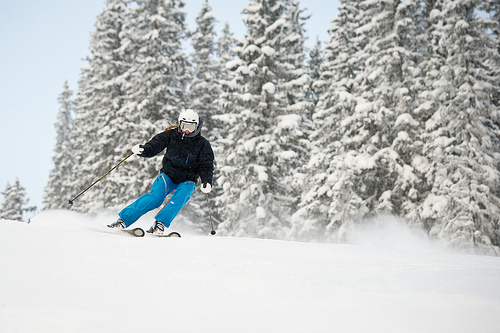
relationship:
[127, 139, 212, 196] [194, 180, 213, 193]
gloves on skiers hands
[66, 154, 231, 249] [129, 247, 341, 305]
skis on snow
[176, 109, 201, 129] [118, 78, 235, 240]
helmet on skier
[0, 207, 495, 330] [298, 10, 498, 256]
snow on trees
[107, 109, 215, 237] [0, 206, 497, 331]
lady on hill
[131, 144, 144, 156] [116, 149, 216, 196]
gloves on hands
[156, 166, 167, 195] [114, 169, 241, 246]
zipper on pants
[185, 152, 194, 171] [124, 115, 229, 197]
line on jacket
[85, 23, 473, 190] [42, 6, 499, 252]
snow on trees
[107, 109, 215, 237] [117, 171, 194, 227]
lady wears pants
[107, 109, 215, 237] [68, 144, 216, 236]
lady holds black poles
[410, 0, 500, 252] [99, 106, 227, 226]
pine tree behind skier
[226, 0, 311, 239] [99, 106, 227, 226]
pine tree behind skier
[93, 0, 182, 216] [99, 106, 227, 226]
pine tree behind skier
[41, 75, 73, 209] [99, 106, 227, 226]
pine tree behind skier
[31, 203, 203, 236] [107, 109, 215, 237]
puff kicked up by lady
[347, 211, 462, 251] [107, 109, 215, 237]
puff kicked up by lady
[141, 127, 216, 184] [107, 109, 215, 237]
jacket on lady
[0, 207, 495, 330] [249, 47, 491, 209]
snow on trees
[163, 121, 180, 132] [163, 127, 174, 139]
hair on shoulder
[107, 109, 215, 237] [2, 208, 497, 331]
lady in snow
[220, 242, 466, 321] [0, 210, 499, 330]
snow on ground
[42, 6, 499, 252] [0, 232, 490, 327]
trees covered in snow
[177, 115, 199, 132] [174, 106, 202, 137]
eyeprotector of face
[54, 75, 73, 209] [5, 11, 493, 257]
pine tree in background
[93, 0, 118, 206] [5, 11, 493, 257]
pine tree in background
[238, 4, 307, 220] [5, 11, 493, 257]
pine tree in background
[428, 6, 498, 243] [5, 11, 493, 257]
pine tree in background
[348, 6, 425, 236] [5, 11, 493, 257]
pine tree in background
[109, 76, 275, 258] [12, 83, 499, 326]
lady playing game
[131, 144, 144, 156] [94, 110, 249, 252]
gloves for skatting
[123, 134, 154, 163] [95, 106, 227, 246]
gloves for skatting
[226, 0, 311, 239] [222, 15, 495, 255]
pine tree covered by snow